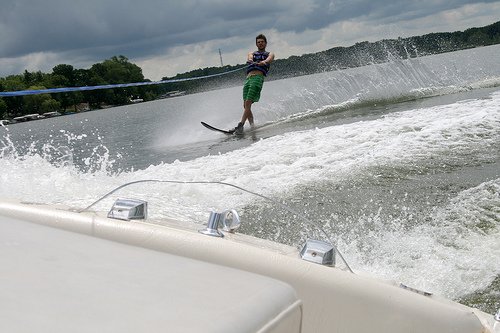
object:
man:
[227, 33, 278, 135]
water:
[363, 59, 500, 264]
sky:
[0, 1, 498, 79]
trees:
[331, 46, 354, 69]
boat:
[0, 179, 497, 332]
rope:
[1, 60, 263, 98]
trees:
[95, 56, 143, 106]